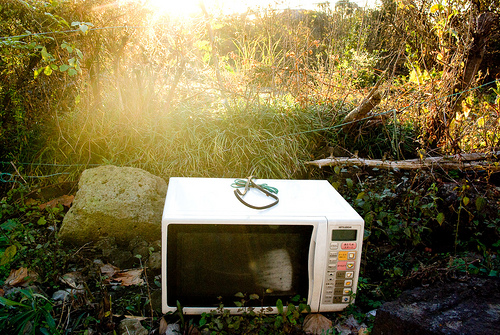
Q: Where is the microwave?
A: Outdoors on the ground.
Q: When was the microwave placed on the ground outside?
A: Sunny afternoon.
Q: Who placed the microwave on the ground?
A: Homeowner.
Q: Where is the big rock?
A: Behind the microwave.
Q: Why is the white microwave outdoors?
A: Broken.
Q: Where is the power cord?
A: On top of the microwave.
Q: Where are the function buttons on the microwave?
A: Front right side.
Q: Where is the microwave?
A: On the ground.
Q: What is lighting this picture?
A: The sun.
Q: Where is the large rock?
A: To the left behind the microwave.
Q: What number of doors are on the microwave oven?
A: One.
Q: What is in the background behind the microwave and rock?
A: Trees and grasses.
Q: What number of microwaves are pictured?
A: One.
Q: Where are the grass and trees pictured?
A: Behind the rock and microwave.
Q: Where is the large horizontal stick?
A: On the ground behind the microwave.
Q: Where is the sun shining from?
A: From behind the microwave?.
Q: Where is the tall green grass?
A: Behind the microwave.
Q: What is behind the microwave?
A: Rocks and grass.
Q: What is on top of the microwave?
A: A electric plug.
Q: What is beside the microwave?
A: A big rock.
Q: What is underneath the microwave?
A: The ground.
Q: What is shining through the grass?
A: The sun.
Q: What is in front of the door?
A: Plants.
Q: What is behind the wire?
A: Grass and weeds.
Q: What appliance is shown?
A: Microwave.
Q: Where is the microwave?
A: In the woods.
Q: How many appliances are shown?
A: One.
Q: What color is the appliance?
A: White.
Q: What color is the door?
A: Black.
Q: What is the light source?
A: The sun.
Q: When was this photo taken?
A: During the daytime.